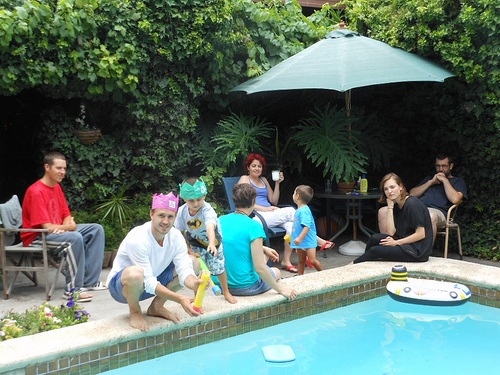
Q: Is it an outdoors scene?
A: Yes, it is outdoors.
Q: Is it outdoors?
A: Yes, it is outdoors.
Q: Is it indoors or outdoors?
A: It is outdoors.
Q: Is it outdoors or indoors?
A: It is outdoors.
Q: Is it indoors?
A: No, it is outdoors.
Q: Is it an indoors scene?
A: No, it is outdoors.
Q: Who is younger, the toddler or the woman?
A: The toddler is younger than the woman.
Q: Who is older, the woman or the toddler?
A: The woman is older than the toddler.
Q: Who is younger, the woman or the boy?
A: The boy is younger than the woman.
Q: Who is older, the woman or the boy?
A: The woman is older than the boy.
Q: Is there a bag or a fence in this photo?
A: No, there are no fences or bags.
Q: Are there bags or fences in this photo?
A: No, there are no fences or bags.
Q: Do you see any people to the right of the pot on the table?
A: Yes, there is a person to the right of the pot.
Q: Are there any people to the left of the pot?
A: No, the person is to the right of the pot.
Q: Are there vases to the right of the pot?
A: No, there is a person to the right of the pot.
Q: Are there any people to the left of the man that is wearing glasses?
A: Yes, there is a person to the left of the man.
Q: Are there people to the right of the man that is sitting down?
A: No, the person is to the left of the man.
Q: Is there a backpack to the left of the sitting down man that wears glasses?
A: No, there is a person to the left of the man.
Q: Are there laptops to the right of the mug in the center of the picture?
A: No, there is a person to the right of the mug.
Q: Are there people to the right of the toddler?
A: Yes, there is a person to the right of the toddler.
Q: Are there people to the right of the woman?
A: Yes, there is a person to the right of the woman.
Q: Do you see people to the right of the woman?
A: Yes, there is a person to the right of the woman.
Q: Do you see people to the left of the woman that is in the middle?
A: No, the person is to the right of the woman.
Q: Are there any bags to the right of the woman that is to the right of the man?
A: No, there is a person to the right of the woman.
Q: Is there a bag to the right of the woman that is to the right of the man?
A: No, there is a person to the right of the woman.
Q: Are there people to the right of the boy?
A: Yes, there is a person to the right of the boy.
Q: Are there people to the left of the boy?
A: No, the person is to the right of the boy.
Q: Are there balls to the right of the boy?
A: No, there is a person to the right of the boy.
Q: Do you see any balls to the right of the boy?
A: No, there is a person to the right of the boy.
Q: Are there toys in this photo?
A: Yes, there is a toy.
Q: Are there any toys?
A: Yes, there is a toy.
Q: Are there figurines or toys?
A: Yes, there is a toy.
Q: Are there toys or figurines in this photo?
A: Yes, there is a toy.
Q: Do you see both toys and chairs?
A: Yes, there are both a toy and a chair.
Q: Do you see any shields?
A: No, there are no shields.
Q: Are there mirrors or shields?
A: No, there are no shields or mirrors.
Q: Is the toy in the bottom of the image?
A: Yes, the toy is in the bottom of the image.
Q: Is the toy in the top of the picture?
A: No, the toy is in the bottom of the image.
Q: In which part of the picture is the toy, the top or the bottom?
A: The toy is in the bottom of the image.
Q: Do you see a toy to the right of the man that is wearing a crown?
A: Yes, there is a toy to the right of the man.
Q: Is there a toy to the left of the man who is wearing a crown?
A: No, the toy is to the right of the man.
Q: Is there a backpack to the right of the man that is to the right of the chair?
A: No, there is a toy to the right of the man.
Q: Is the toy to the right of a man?
A: Yes, the toy is to the right of a man.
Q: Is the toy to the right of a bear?
A: No, the toy is to the right of a man.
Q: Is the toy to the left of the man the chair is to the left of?
A: No, the toy is to the right of the man.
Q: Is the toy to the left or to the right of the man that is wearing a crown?
A: The toy is to the right of the man.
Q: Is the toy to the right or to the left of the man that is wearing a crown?
A: The toy is to the right of the man.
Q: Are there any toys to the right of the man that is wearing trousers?
A: Yes, there is a toy to the right of the man.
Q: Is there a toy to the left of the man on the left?
A: No, the toy is to the right of the man.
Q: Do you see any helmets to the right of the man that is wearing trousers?
A: No, there is a toy to the right of the man.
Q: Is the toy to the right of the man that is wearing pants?
A: Yes, the toy is to the right of the man.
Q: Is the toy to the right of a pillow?
A: No, the toy is to the right of the man.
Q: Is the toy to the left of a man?
A: No, the toy is to the right of a man.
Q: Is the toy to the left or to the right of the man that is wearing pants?
A: The toy is to the right of the man.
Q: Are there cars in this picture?
A: No, there are no cars.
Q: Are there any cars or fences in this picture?
A: No, there are no cars or fences.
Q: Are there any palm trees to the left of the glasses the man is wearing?
A: Yes, there are palm trees to the left of the glasses.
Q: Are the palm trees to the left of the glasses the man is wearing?
A: Yes, the palm trees are to the left of the glasses.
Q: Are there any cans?
A: No, there are no cans.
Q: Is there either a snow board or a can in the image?
A: No, there are no cans or snowboards.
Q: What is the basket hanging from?
A: The basket is hanging from the tree.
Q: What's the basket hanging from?
A: The basket is hanging from the tree.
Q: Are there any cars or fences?
A: No, there are no fences or cars.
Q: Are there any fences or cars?
A: No, there are no fences or cars.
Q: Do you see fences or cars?
A: No, there are no fences or cars.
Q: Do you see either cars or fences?
A: No, there are no fences or cars.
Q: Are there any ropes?
A: No, there are no ropes.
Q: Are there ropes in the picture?
A: No, there are no ropes.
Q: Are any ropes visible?
A: No, there are no ropes.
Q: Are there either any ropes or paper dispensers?
A: No, there are no ropes or paper dispensers.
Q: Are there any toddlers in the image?
A: Yes, there is a toddler.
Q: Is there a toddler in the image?
A: Yes, there is a toddler.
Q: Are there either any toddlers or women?
A: Yes, there is a toddler.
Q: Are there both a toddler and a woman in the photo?
A: Yes, there are both a toddler and a woman.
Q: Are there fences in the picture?
A: No, there are no fences.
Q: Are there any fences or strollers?
A: No, there are no fences or strollers.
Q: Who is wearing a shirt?
A: The toddler is wearing a shirt.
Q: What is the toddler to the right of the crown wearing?
A: The toddler is wearing a shirt.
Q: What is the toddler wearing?
A: The toddler is wearing a shirt.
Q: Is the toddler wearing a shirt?
A: Yes, the toddler is wearing a shirt.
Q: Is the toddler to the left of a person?
A: Yes, the toddler is to the left of a person.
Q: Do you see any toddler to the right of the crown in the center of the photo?
A: Yes, there is a toddler to the right of the crown.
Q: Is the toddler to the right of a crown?
A: Yes, the toddler is to the right of a crown.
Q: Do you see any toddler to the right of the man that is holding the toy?
A: Yes, there is a toddler to the right of the man.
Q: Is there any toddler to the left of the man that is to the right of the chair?
A: No, the toddler is to the right of the man.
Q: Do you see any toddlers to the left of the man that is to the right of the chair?
A: No, the toddler is to the right of the man.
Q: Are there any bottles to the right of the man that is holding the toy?
A: No, there is a toddler to the right of the man.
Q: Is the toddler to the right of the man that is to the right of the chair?
A: Yes, the toddler is to the right of the man.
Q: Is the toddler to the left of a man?
A: No, the toddler is to the right of a man.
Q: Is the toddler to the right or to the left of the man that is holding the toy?
A: The toddler is to the right of the man.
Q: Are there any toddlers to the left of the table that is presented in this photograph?
A: Yes, there is a toddler to the left of the table.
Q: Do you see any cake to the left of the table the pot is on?
A: No, there is a toddler to the left of the table.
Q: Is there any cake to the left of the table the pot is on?
A: No, there is a toddler to the left of the table.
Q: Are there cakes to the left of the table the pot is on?
A: No, there is a toddler to the left of the table.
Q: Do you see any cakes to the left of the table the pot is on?
A: No, there is a toddler to the left of the table.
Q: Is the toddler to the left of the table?
A: Yes, the toddler is to the left of the table.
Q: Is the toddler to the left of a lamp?
A: No, the toddler is to the left of the table.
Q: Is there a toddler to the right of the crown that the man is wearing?
A: Yes, there is a toddler to the right of the crown.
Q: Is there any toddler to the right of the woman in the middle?
A: Yes, there is a toddler to the right of the woman.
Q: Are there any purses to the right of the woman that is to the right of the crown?
A: No, there is a toddler to the right of the woman.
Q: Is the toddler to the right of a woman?
A: Yes, the toddler is to the right of a woman.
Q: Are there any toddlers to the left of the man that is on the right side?
A: Yes, there is a toddler to the left of the man.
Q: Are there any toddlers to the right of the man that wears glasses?
A: No, the toddler is to the left of the man.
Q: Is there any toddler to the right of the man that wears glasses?
A: No, the toddler is to the left of the man.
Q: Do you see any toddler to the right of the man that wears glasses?
A: No, the toddler is to the left of the man.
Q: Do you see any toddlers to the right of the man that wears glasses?
A: No, the toddler is to the left of the man.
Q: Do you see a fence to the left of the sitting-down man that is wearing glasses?
A: No, there is a toddler to the left of the man.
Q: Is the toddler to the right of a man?
A: No, the toddler is to the left of a man.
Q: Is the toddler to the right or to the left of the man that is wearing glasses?
A: The toddler is to the left of the man.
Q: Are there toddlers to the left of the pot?
A: Yes, there is a toddler to the left of the pot.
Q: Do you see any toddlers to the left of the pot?
A: Yes, there is a toddler to the left of the pot.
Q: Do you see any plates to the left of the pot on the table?
A: No, there is a toddler to the left of the pot.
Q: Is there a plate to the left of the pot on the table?
A: No, there is a toddler to the left of the pot.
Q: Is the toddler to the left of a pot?
A: Yes, the toddler is to the left of a pot.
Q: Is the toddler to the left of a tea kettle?
A: No, the toddler is to the left of a pot.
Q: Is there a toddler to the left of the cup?
A: Yes, there is a toddler to the left of the cup.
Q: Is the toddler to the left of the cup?
A: Yes, the toddler is to the left of the cup.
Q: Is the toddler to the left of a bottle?
A: No, the toddler is to the left of the cup.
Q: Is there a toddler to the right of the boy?
A: Yes, there is a toddler to the right of the boy.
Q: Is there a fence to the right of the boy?
A: No, there is a toddler to the right of the boy.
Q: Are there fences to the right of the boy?
A: No, there is a toddler to the right of the boy.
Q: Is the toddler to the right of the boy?
A: Yes, the toddler is to the right of the boy.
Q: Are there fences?
A: No, there are no fences.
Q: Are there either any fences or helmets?
A: No, there are no fences or helmets.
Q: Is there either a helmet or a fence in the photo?
A: No, there are no fences or helmets.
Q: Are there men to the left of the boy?
A: Yes, there is a man to the left of the boy.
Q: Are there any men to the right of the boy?
A: No, the man is to the left of the boy.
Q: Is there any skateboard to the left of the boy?
A: No, there is a man to the left of the boy.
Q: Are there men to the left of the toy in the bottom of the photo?
A: Yes, there is a man to the left of the toy.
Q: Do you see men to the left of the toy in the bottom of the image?
A: Yes, there is a man to the left of the toy.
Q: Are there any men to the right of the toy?
A: No, the man is to the left of the toy.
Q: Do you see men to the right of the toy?
A: No, the man is to the left of the toy.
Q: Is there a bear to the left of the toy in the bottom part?
A: No, there is a man to the left of the toy.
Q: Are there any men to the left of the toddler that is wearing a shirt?
A: Yes, there is a man to the left of the toddler.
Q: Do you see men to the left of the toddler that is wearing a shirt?
A: Yes, there is a man to the left of the toddler.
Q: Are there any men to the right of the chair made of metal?
A: Yes, there is a man to the right of the chair.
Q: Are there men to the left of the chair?
A: No, the man is to the right of the chair.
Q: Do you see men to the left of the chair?
A: No, the man is to the right of the chair.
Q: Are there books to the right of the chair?
A: No, there is a man to the right of the chair.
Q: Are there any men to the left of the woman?
A: Yes, there is a man to the left of the woman.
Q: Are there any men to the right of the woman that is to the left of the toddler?
A: No, the man is to the left of the woman.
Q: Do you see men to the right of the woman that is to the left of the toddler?
A: No, the man is to the left of the woman.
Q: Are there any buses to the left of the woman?
A: No, there is a man to the left of the woman.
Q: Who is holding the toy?
A: The man is holding the toy.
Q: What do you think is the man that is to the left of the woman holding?
A: The man is holding the toy.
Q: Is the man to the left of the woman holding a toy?
A: Yes, the man is holding a toy.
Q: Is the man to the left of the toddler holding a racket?
A: No, the man is holding a toy.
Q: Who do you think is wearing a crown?
A: The man is wearing a crown.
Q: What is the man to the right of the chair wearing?
A: The man is wearing a crown.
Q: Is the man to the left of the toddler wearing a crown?
A: Yes, the man is wearing a crown.